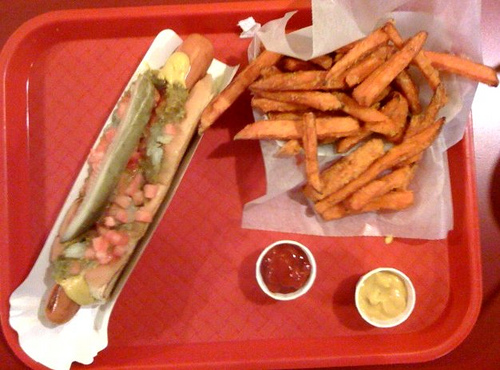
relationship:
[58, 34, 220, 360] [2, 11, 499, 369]
hotdog on top of tray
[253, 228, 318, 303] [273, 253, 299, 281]
cup has ketchup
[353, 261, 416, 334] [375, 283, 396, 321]
cup has mustard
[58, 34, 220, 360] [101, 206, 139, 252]
hotdog has tomatoes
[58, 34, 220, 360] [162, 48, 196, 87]
hotdog has mustard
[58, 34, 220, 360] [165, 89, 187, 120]
hotdog has relish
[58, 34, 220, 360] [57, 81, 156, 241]
hotdog has pickle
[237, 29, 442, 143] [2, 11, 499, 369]
sweet potato fries on top of tray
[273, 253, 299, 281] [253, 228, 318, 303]
ketchup inside cup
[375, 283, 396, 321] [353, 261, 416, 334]
mustard inside cup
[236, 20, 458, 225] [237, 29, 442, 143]
paper tray underneath sweet potato fries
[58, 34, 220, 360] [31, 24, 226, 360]
hotdog inside paper tray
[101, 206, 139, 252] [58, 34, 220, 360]
tomatoes on top of hotdog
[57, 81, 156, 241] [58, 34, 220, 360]
pickle on top of hotdog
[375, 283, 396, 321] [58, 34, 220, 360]
mustard on top of hotdog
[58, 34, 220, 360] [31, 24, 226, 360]
hotdog in paper tray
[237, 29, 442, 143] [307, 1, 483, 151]
sweet potato fries on top of parchment paper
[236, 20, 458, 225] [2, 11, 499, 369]
paper tray on top of tray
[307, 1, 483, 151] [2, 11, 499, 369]
parchment paper on top of tray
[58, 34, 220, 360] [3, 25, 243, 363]
hotdog in paper tray